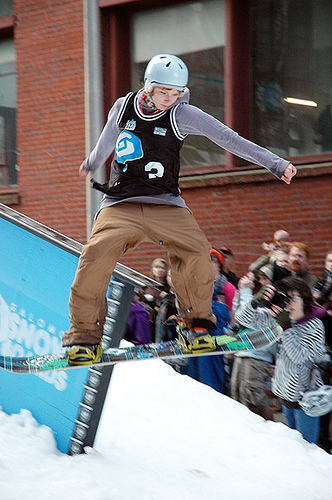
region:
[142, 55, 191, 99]
girl wearing a blue helmet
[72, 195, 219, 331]
girl wearing brown pants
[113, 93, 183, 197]
girl wearing a black jersey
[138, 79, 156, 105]
girl with blond hair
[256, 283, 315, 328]
person taking a photo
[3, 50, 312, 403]
this is a snowboarder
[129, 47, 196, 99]
rider wearing a helmet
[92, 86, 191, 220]
a black and white jersey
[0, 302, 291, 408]
this is a snowboard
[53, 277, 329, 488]
snow on the ground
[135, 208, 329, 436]
spectators in the background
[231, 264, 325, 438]
this is a woman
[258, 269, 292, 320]
this is a camera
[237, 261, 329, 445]
woman is taking a picture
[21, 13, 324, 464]
rider is doing a trick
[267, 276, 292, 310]
the camera is black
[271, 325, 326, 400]
the sweater is striped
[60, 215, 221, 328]
the pants are khaki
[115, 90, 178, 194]
the vest is black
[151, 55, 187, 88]
the helmet is white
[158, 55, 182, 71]
holes in the helmet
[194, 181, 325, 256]
the building is brick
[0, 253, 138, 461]
the wall in the snow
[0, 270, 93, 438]
the wall is blue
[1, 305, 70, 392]
the words are white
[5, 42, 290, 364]
woman perfroming a snowboarding trick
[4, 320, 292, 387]
black, green, and blue snowboard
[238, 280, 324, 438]
woman taking a picture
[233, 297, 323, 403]
black and white striped coat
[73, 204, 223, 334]
brown pants snowboarder is wearing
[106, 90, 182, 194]
black and white jersey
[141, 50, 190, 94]
gray helmet snowboarder is wearing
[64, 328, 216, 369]
yellow snow boats snowboarder is wearing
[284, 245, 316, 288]
man with red hair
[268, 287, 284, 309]
camera person is using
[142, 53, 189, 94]
a snowboarder's helmet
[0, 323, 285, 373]
plaid pattern snowboard deck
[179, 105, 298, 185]
a snowboarder's left arm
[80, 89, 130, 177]
a snowboarder's right arm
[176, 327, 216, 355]
a snowboarder's left boot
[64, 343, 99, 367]
a snowboarder's right boot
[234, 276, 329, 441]
woman wearing glasses taking picture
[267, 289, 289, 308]
a photographer's camera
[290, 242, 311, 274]
man with red hair and a beard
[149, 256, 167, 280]
woman spectating in a crowd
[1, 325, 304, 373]
The snowboarder is on a long board.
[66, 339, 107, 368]
The left yellow footing.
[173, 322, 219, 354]
The right yellow footing.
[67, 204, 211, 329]
The man is wearing a brown pant.